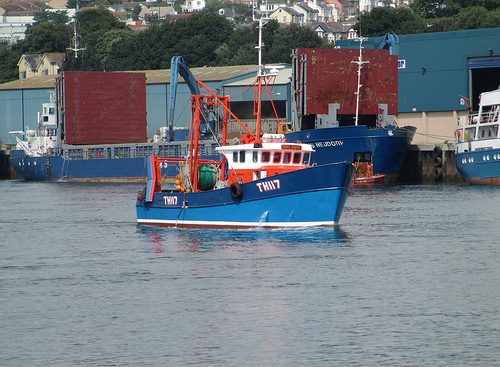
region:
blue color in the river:
[131, 266, 305, 313]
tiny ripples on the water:
[126, 250, 274, 285]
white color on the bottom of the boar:
[203, 214, 295, 226]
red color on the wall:
[76, 89, 130, 139]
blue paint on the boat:
[273, 204, 315, 216]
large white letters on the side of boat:
[256, 177, 285, 192]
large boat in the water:
[133, 50, 393, 248]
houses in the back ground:
[280, 1, 344, 23]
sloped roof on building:
[38, 49, 63, 64]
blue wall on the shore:
[61, 137, 175, 161]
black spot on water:
[179, 263, 246, 315]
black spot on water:
[324, 268, 366, 283]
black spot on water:
[401, 232, 427, 253]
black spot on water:
[418, 282, 450, 326]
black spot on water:
[88, 242, 143, 291]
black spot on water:
[76, 305, 110, 330]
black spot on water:
[54, 243, 114, 305]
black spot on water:
[33, 305, 83, 345]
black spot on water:
[106, 297, 147, 342]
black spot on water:
[182, 302, 226, 340]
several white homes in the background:
[233, 5, 346, 47]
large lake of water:
[27, 263, 410, 351]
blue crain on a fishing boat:
[102, 37, 261, 188]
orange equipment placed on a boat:
[100, 51, 332, 217]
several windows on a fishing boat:
[173, 108, 389, 212]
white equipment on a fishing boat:
[311, 26, 428, 143]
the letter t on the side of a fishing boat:
[92, 92, 405, 257]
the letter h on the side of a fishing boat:
[96, 133, 376, 260]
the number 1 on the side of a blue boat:
[91, 115, 383, 258]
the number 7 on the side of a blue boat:
[158, 142, 403, 242]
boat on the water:
[105, 55, 370, 237]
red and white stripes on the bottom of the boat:
[136, 213, 337, 232]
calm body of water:
[3, 176, 498, 366]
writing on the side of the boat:
[246, 178, 291, 195]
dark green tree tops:
[1, 6, 326, 73]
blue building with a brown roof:
[2, 62, 266, 132]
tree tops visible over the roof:
[1, 1, 318, 94]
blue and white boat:
[441, 81, 499, 186]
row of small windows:
[230, 150, 312, 166]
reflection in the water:
[132, 225, 336, 251]